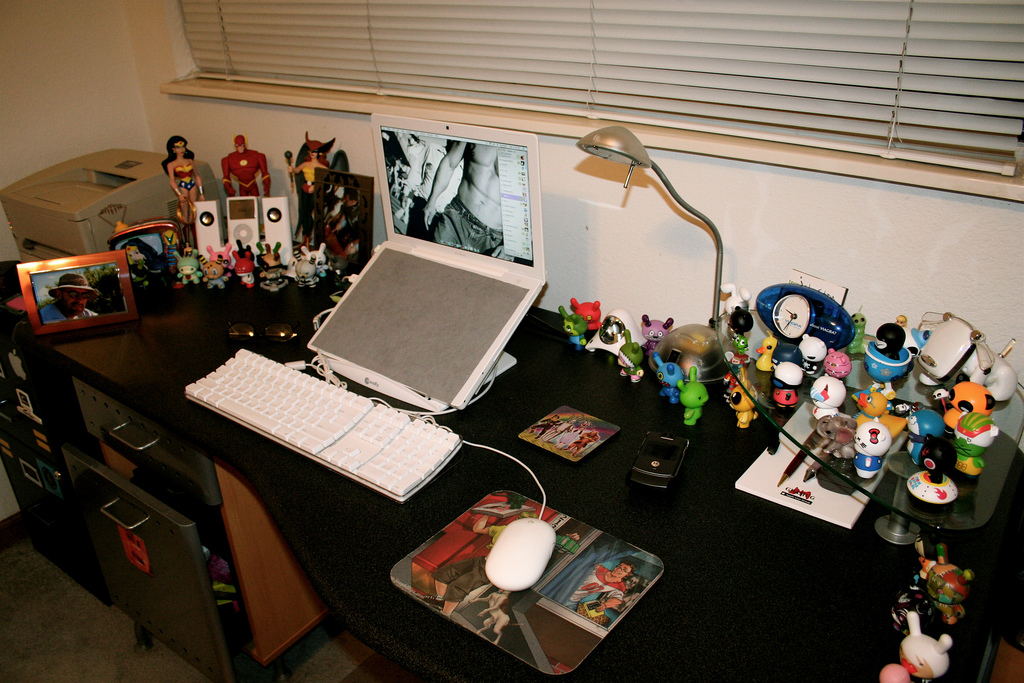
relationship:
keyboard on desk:
[186, 346, 465, 503] [3, 234, 1022, 678]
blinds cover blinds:
[174, 1, 1022, 179] [158, 0, 1024, 204]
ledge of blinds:
[159, 76, 1022, 204] [158, 0, 1024, 204]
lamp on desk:
[572, 124, 728, 387] [3, 234, 1022, 678]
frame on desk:
[18, 245, 137, 335] [3, 234, 1022, 678]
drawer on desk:
[60, 446, 242, 680] [3, 234, 1022, 678]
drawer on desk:
[67, 371, 224, 512] [3, 234, 1022, 678]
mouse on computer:
[486, 516, 556, 589] [304, 111, 549, 415]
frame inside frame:
[16, 248, 137, 335] [18, 245, 137, 335]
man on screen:
[423, 139, 518, 261] [379, 125, 534, 265]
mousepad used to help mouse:
[384, 486, 664, 676] [486, 516, 556, 589]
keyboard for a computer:
[186, 346, 465, 503] [304, 111, 549, 415]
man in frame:
[36, 266, 103, 321] [16, 248, 137, 335]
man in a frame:
[36, 266, 103, 321] [18, 245, 137, 335]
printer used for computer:
[3, 146, 226, 265] [304, 111, 549, 415]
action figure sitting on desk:
[953, 411, 999, 476] [3, 234, 1022, 678]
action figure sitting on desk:
[568, 297, 603, 332] [3, 234, 1022, 678]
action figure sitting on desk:
[559, 304, 586, 352] [3, 234, 1022, 678]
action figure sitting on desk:
[853, 414, 891, 476] [3, 234, 1022, 678]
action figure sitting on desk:
[676, 364, 708, 428] [3, 234, 1022, 678]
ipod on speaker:
[226, 194, 262, 255] [262, 196, 294, 263]